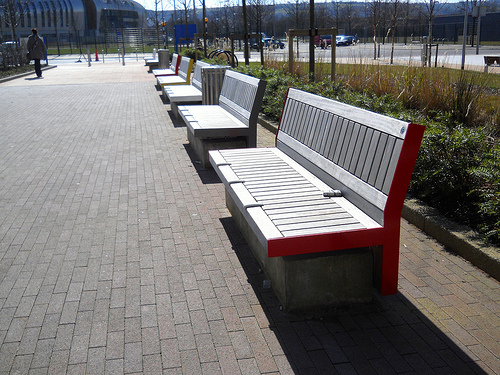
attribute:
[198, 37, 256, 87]
rack — bike, empty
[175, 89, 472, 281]
bench — lined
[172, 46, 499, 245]
bushes — green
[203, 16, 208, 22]
spotlight — long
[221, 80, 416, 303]
bench — lined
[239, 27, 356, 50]
vehicles — parked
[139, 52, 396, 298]
benches — lined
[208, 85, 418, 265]
benches — lined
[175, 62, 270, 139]
benches — lined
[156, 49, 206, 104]
benches — lined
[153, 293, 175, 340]
bricks — grey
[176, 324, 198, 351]
bricks — grey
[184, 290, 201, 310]
bricks — grey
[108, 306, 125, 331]
bricks — grey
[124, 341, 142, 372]
bricks — grey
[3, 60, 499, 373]
walkway — brick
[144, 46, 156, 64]
bench — lined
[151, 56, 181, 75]
bench — lined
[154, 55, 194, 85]
bench — lined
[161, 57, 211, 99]
bench — lined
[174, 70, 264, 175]
bench — lined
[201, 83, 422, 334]
bench — lined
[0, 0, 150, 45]
building — distant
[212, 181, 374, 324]
block — concrete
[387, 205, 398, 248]
paint — red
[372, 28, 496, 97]
flowers — growing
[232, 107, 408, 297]
bench — red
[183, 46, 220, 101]
can — grey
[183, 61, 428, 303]
benches — lined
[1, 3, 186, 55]
stadium — large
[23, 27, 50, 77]
person — walking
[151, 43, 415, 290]
benches — lined